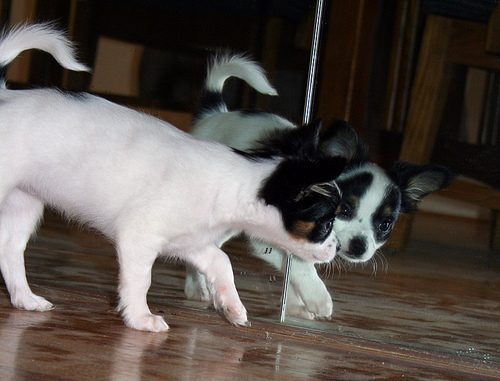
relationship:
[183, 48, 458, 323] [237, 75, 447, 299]
dog walking next to dog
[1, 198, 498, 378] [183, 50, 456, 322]
floor beneath dogs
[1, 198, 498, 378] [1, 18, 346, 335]
floor beneath dogs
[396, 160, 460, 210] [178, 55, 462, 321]
ear of dog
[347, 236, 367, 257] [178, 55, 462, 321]
nose on dog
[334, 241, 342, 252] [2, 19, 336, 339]
nose on dog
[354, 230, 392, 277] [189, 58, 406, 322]
whiskers on dog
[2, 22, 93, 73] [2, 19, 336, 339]
end on dog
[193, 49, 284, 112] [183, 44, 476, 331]
tail on dog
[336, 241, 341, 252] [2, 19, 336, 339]
nose on dog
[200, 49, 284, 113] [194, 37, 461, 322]
tail on dog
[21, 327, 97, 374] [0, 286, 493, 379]
dust on floor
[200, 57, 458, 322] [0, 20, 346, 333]
reflection of a puppy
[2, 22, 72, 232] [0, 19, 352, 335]
end of a dog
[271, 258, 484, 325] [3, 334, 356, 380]
reflection of wood floor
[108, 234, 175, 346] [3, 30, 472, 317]
leg of  a dog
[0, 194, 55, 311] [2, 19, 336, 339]
leg of  a dog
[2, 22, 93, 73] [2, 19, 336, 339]
end of  a dog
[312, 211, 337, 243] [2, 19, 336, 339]
eye of dog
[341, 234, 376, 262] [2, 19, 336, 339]
nose of dog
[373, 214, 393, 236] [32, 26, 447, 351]
eye of dog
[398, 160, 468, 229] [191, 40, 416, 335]
ear of dog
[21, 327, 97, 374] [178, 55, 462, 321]
dust of dog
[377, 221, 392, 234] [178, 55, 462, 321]
eye of dog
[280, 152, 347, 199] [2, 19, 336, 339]
ear of dog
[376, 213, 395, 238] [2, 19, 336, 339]
eye of dog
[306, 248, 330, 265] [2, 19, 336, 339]
mouth of dog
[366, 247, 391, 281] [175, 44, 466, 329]
whiskers of puppy